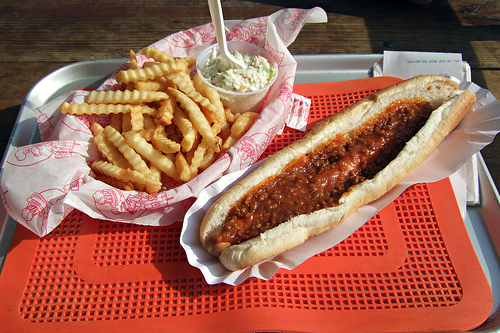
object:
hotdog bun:
[200, 74, 479, 273]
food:
[198, 73, 476, 270]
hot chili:
[208, 97, 436, 245]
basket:
[56, 19, 296, 214]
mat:
[2, 77, 495, 333]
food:
[7, 1, 497, 286]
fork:
[205, 0, 246, 70]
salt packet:
[201, 52, 275, 95]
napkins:
[369, 49, 482, 210]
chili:
[215, 98, 431, 249]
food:
[62, 49, 478, 270]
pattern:
[163, 22, 216, 50]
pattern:
[7, 141, 81, 167]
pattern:
[237, 125, 282, 167]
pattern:
[91, 187, 181, 221]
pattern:
[21, 177, 83, 226]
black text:
[407, 58, 460, 63]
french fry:
[60, 47, 259, 195]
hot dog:
[212, 97, 430, 250]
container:
[195, 38, 277, 112]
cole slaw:
[201, 49, 275, 92]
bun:
[199, 75, 478, 273]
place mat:
[0, 77, 494, 333]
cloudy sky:
[120, 55, 187, 187]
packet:
[285, 92, 311, 133]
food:
[280, 69, 475, 251]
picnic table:
[0, 0, 499, 333]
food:
[59, 61, 442, 256]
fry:
[62, 48, 259, 193]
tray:
[0, 54, 500, 330]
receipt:
[381, 51, 463, 83]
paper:
[0, 5, 499, 289]